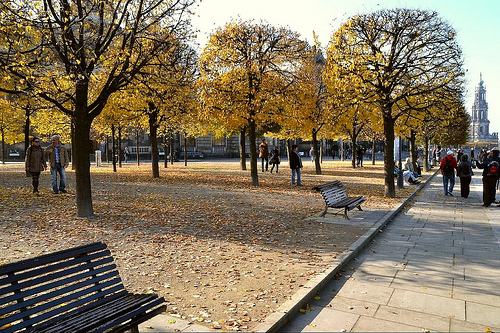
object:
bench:
[0, 240, 167, 332]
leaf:
[1, 158, 438, 333]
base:
[301, 195, 393, 228]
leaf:
[320, 4, 468, 200]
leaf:
[182, 17, 330, 188]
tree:
[3, 0, 198, 221]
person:
[457, 152, 476, 200]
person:
[476, 146, 499, 205]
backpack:
[482, 159, 499, 182]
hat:
[444, 148, 457, 157]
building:
[463, 71, 500, 160]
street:
[249, 157, 500, 333]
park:
[2, 2, 497, 333]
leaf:
[312, 292, 323, 302]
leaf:
[363, 302, 373, 312]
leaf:
[376, 227, 384, 234]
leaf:
[249, 270, 258, 280]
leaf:
[327, 241, 338, 249]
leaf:
[325, 23, 347, 38]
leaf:
[327, 48, 335, 54]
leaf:
[326, 78, 340, 89]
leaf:
[369, 122, 382, 131]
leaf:
[322, 103, 331, 109]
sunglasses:
[31, 138, 42, 145]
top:
[478, 70, 487, 86]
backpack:
[438, 156, 457, 177]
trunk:
[249, 125, 257, 185]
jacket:
[23, 144, 50, 179]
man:
[45, 132, 69, 193]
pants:
[47, 166, 70, 194]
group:
[436, 147, 477, 200]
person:
[392, 157, 420, 186]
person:
[405, 154, 415, 181]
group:
[389, 153, 422, 185]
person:
[286, 141, 308, 188]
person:
[257, 137, 270, 172]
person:
[268, 143, 283, 175]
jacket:
[476, 160, 500, 184]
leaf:
[209, 37, 220, 45]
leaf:
[17, 57, 26, 70]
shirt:
[436, 155, 459, 175]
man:
[438, 149, 458, 196]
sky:
[199, 0, 342, 19]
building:
[281, 40, 392, 164]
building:
[19, 13, 186, 161]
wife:
[20, 136, 49, 198]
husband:
[45, 132, 71, 196]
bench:
[310, 179, 368, 221]